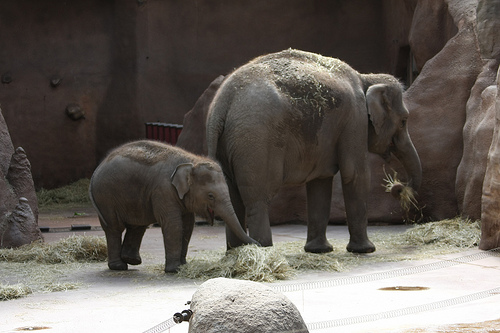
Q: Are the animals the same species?
A: Yes, all the animals are elephants.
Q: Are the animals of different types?
A: No, all the animals are elephants.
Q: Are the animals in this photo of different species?
A: No, all the animals are elephants.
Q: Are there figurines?
A: No, there are no figurines.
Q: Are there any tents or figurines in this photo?
A: No, there are no figurines or tents.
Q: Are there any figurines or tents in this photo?
A: No, there are no figurines or tents.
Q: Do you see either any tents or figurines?
A: No, there are no figurines or tents.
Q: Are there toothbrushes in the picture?
A: No, there are no toothbrushes.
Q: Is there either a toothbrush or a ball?
A: No, there are no toothbrushes or balls.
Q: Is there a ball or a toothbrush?
A: No, there are no toothbrushes or balls.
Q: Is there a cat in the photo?
A: No, there are no cats.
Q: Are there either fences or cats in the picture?
A: No, there are no cats or fences.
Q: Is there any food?
A: Yes, there is food.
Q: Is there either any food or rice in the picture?
A: Yes, there is food.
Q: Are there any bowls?
A: No, there are no bowls.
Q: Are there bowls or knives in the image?
A: No, there are no bowls or knives.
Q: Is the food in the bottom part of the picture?
A: Yes, the food is in the bottom of the image.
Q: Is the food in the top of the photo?
A: No, the food is in the bottom of the image.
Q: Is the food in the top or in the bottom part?
A: The food is in the bottom of the image.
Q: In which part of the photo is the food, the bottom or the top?
A: The food is in the bottom of the image.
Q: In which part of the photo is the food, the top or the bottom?
A: The food is in the bottom of the image.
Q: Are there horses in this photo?
A: No, there are no horses.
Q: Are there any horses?
A: No, there are no horses.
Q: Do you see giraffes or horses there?
A: No, there are no horses or giraffes.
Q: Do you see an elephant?
A: Yes, there is an elephant.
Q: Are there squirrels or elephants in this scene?
A: Yes, there is an elephant.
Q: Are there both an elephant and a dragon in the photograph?
A: No, there is an elephant but no dragons.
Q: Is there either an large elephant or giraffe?
A: Yes, there is a large elephant.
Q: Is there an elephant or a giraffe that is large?
A: Yes, the elephant is large.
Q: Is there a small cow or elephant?
A: Yes, there is a small elephant.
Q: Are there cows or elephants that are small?
A: Yes, the elephant is small.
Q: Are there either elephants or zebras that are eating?
A: Yes, the elephant is eating.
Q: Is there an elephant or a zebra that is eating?
A: Yes, the elephant is eating.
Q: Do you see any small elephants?
A: Yes, there is a small elephant.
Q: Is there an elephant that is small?
A: Yes, there is an elephant that is small.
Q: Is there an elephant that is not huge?
A: Yes, there is a small elephant.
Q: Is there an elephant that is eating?
A: Yes, there is an elephant that is eating.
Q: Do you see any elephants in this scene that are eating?
A: Yes, there is an elephant that is eating.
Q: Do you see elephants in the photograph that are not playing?
A: Yes, there is an elephant that is eating .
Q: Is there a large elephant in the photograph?
A: Yes, there is a large elephant.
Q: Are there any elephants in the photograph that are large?
A: Yes, there is a large elephant.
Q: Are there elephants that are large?
A: Yes, there is an elephant that is large.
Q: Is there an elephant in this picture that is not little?
A: Yes, there is a large elephant.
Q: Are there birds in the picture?
A: No, there are no birds.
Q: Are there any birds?
A: No, there are no birds.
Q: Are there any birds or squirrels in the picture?
A: No, there are no birds or squirrels.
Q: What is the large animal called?
A: The animal is an elephant.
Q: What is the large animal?
A: The animal is an elephant.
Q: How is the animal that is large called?
A: The animal is an elephant.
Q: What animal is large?
A: The animal is an elephant.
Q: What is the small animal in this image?
A: The animal is an elephant.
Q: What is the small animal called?
A: The animal is an elephant.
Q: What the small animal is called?
A: The animal is an elephant.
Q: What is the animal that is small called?
A: The animal is an elephant.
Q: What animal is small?
A: The animal is an elephant.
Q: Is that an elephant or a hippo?
A: That is an elephant.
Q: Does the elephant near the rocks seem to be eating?
A: Yes, the elephant is eating.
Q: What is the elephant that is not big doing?
A: The elephant is eating.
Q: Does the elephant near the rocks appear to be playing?
A: No, the elephant is eating.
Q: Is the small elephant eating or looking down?
A: The elephant is eating.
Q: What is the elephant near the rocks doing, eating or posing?
A: The elephant is eating.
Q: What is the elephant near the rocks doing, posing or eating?
A: The elephant is eating.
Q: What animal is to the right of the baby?
A: The animal is an elephant.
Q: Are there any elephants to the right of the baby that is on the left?
A: Yes, there is an elephant to the right of the baby.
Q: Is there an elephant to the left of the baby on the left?
A: No, the elephant is to the right of the baby.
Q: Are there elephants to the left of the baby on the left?
A: No, the elephant is to the right of the baby.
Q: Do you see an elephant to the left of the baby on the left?
A: No, the elephant is to the right of the baby.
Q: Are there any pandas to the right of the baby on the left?
A: No, there is an elephant to the right of the baby.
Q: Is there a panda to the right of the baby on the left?
A: No, there is an elephant to the right of the baby.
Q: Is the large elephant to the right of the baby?
A: Yes, the elephant is to the right of the baby.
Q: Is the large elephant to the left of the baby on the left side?
A: No, the elephant is to the right of the baby.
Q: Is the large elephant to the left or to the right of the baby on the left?
A: The elephant is to the right of the baby.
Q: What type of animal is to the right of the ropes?
A: The animal is an elephant.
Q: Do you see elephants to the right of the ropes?
A: Yes, there is an elephant to the right of the ropes.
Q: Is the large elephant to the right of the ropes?
A: Yes, the elephant is to the right of the ropes.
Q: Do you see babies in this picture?
A: Yes, there is a baby.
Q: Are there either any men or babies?
A: Yes, there is a baby.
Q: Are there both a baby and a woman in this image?
A: No, there is a baby but no women.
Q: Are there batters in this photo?
A: No, there are no batters.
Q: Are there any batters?
A: No, there are no batters.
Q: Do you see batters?
A: No, there are no batters.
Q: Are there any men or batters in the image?
A: No, there are no batters or men.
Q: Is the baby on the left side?
A: Yes, the baby is on the left of the image.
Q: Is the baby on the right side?
A: No, the baby is on the left of the image.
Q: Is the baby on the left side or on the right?
A: The baby is on the left of the image.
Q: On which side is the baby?
A: The baby is on the left of the image.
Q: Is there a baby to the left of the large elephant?
A: Yes, there is a baby to the left of the elephant.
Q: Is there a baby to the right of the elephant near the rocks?
A: No, the baby is to the left of the elephant.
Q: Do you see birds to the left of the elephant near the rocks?
A: No, there is a baby to the left of the elephant.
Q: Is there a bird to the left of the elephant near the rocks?
A: No, there is a baby to the left of the elephant.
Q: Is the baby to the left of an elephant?
A: Yes, the baby is to the left of an elephant.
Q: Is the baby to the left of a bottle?
A: No, the baby is to the left of an elephant.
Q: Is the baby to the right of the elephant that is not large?
A: No, the baby is to the left of the elephant.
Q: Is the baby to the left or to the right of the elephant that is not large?
A: The baby is to the left of the elephant.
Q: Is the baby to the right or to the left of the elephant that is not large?
A: The baby is to the left of the elephant.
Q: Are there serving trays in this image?
A: No, there are no serving trays.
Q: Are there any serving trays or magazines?
A: No, there are no serving trays or magazines.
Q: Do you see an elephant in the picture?
A: Yes, there are elephants.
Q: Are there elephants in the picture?
A: Yes, there are elephants.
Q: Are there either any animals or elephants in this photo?
A: Yes, there are elephants.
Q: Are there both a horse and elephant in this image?
A: No, there are elephants but no horses.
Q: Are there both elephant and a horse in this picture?
A: No, there are elephants but no horses.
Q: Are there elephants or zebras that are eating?
A: Yes, the elephants are eating.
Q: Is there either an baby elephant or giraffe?
A: Yes, there are baby elephants.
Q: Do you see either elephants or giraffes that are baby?
A: Yes, the elephants are baby.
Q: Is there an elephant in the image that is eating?
A: Yes, there are elephants that are eating.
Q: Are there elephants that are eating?
A: Yes, there are elephants that are eating.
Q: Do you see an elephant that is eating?
A: Yes, there are elephants that are eating.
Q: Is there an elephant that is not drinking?
A: Yes, there are elephants that are eating.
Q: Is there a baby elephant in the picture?
A: Yes, there are baby elephants.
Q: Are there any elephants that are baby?
A: Yes, there are elephants that are baby.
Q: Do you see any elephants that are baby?
A: Yes, there are elephants that are baby.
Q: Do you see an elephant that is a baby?
A: Yes, there are elephants that are baby.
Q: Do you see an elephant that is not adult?
A: Yes, there are baby elephants.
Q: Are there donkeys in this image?
A: No, there are no donkeys.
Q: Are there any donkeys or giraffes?
A: No, there are no donkeys or giraffes.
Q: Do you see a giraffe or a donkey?
A: No, there are no donkeys or giraffes.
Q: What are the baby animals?
A: The animals are elephants.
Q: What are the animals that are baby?
A: The animals are elephants.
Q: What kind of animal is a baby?
A: The animal is elephants.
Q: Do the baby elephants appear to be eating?
A: Yes, the elephants are eating.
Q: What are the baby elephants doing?
A: The elephants are eating.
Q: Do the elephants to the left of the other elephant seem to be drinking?
A: No, the elephants are eating.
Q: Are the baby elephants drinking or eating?
A: The elephants are eating.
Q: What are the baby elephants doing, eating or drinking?
A: The elephants are eating.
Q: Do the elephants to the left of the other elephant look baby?
A: Yes, the elephants are baby.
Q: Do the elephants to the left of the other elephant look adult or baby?
A: The elephants are baby.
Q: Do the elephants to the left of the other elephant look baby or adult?
A: The elephants are baby.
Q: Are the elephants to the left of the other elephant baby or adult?
A: The elephants are baby.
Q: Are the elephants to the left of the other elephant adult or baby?
A: The elephants are baby.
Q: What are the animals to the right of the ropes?
A: The animals are elephants.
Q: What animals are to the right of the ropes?
A: The animals are elephants.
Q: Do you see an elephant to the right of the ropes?
A: Yes, there are elephants to the right of the ropes.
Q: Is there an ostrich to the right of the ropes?
A: No, there are elephants to the right of the ropes.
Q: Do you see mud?
A: Yes, there is mud.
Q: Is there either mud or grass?
A: Yes, there is mud.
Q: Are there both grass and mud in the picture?
A: Yes, there are both mud and grass.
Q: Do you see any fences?
A: No, there are no fences.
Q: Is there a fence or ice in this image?
A: No, there are no fences or ice.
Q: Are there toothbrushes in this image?
A: No, there are no toothbrushes.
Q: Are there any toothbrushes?
A: No, there are no toothbrushes.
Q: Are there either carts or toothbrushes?
A: No, there are no toothbrushes or carts.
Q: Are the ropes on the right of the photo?
A: No, the ropes are on the left of the image.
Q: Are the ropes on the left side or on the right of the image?
A: The ropes are on the left of the image.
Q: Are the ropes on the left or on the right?
A: The ropes are on the left of the image.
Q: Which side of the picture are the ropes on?
A: The ropes are on the left of the image.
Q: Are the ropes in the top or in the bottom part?
A: The ropes are in the bottom of the image.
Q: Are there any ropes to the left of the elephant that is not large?
A: Yes, there are ropes to the left of the elephant.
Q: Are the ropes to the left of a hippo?
A: No, the ropes are to the left of an elephant.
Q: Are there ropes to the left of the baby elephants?
A: Yes, there are ropes to the left of the elephants.